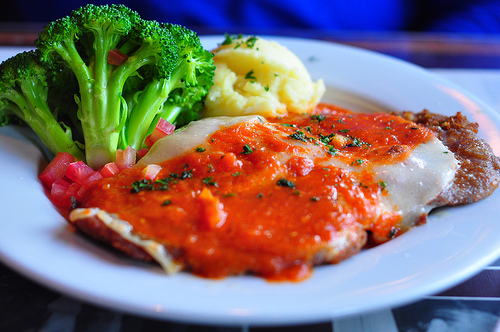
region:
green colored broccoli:
[0, 0, 215, 165]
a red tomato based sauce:
[84, 101, 435, 274]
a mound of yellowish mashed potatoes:
[208, 34, 324, 119]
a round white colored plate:
[0, 32, 496, 323]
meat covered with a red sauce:
[74, 104, 434, 281]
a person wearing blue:
[144, 0, 499, 70]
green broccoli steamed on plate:
[1, 3, 214, 167]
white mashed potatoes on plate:
[198, 33, 325, 115]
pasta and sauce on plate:
[69, 108, 499, 279]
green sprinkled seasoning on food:
[126, 33, 388, 202]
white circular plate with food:
[0, 32, 499, 324]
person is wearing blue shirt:
[20, 1, 498, 68]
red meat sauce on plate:
[386, 109, 499, 204]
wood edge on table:
[1, 25, 499, 52]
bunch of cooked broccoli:
[2, 3, 214, 166]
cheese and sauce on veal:
[70, 103, 499, 275]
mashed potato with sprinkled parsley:
[205, 26, 325, 116]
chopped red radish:
[35, 115, 173, 207]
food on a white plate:
[3, 1, 498, 323]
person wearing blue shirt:
[35, 0, 498, 38]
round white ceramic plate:
[0, 33, 498, 328]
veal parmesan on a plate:
[67, 104, 498, 283]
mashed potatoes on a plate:
[202, 31, 329, 117]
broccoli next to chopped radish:
[2, 3, 212, 213]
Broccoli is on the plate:
[48, 0, 199, 136]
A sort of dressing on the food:
[113, 174, 368, 270]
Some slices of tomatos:
[62, 125, 184, 218]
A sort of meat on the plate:
[203, 145, 473, 255]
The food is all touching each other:
[148, 107, 378, 163]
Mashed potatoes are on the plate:
[209, 78, 378, 146]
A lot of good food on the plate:
[97, 53, 472, 255]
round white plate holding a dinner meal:
[5, 8, 498, 322]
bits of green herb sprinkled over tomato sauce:
[74, 105, 454, 280]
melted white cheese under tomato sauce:
[66, 102, 456, 272]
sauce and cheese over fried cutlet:
[72, 105, 498, 276]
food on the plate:
[30, 33, 456, 280]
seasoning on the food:
[102, 113, 393, 245]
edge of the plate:
[348, 227, 476, 329]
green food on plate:
[12, 6, 215, 146]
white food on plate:
[179, 22, 336, 122]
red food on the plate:
[16, 147, 124, 227]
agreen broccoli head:
[1, 0, 215, 171]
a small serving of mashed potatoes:
[196, 30, 326, 115]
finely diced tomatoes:
[33, 115, 178, 205]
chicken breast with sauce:
[57, 102, 499, 285]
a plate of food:
[0, 10, 495, 326]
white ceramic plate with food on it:
[2, 30, 493, 325]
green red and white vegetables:
[0, 0, 320, 210]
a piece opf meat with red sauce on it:
[69, 100, 497, 280]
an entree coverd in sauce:
[9, 100, 498, 279]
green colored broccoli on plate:
[6, 14, 225, 166]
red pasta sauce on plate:
[86, 103, 447, 275]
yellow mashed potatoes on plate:
[188, 24, 330, 121]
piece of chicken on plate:
[91, 98, 456, 278]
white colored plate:
[5, 29, 499, 320]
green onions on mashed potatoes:
[232, 31, 251, 51]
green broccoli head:
[41, 7, 144, 62]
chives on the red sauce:
[277, 170, 299, 189]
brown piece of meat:
[388, 105, 498, 207]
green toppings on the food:
[133, 148, 228, 202]